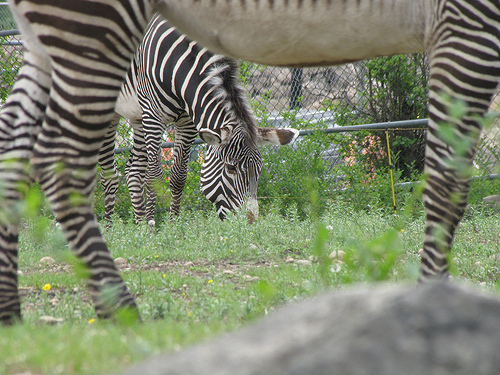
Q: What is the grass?
A: Visible.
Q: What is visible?
A: The grass.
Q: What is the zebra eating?
A: Grass.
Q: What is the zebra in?
A: The field.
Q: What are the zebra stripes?
A: Black and white.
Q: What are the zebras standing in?
A: Grass.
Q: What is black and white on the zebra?
A: Fur.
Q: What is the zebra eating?
A: Grass.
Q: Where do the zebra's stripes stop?
A: Stomach.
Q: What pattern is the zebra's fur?
A: Striped.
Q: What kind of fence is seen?
A: Chain link.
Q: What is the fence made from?
A: Metal.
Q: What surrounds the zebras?
A: Fence.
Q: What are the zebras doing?
A: Grazing.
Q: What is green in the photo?
A: Bushes and grass.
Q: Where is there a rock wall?
A: Behind fence.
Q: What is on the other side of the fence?
A: Rocks.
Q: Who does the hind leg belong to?
A: Zebra.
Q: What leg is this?
A: Front leg.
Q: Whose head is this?
A: Zebra.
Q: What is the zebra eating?
A: Grass.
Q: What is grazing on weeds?
A: Zebra.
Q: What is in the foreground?
A: Boulder.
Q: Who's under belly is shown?
A: Zebra.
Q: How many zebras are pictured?
A: Two.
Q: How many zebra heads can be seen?
A: Two.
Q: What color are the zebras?
A: Black and white.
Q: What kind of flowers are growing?
A: Dandelions.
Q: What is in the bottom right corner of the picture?
A: A rock.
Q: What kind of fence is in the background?
A: Chain link.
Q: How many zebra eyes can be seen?
A: One.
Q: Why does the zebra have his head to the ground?
A: It is eating weeds.